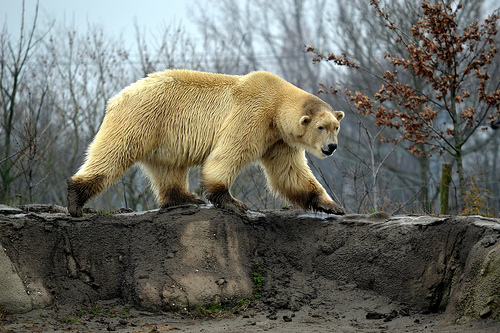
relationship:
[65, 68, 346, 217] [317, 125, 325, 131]
polar bear has eye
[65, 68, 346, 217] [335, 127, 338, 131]
polar bear has eye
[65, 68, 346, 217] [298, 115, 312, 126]
polar bear has ear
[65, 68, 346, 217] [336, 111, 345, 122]
polar bear has ear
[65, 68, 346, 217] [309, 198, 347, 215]
polar bear has paw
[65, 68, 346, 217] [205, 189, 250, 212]
polar bear has paw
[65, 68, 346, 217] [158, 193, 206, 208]
polar bear has paw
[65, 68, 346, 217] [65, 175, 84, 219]
polar bear has paw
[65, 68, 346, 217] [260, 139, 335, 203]
polar bear has leg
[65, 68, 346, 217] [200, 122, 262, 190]
polar bear has leg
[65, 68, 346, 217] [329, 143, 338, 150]
polar bear has nose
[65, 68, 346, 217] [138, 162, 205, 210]
polar bear has leg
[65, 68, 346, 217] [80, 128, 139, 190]
polar bear has leg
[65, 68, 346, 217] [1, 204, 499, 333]
polar bear walk on dirt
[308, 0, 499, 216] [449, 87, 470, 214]
tree has trunk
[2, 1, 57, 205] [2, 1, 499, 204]
tree in background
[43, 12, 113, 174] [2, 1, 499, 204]
tree in background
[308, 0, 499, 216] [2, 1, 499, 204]
tree in background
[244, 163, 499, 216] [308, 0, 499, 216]
fence beside tree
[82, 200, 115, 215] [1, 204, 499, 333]
grass growing in dirt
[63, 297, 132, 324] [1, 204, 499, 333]
grass growing in dirt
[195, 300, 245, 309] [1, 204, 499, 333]
grass growing in dirt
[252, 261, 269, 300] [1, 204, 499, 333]
grass growing in dirt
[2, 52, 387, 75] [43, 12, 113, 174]
power lines above tree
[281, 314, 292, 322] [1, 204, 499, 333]
rock in dirt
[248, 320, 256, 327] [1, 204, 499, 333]
rock in dirt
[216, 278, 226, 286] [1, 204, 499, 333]
rock in dirt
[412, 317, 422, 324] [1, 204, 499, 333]
rock in dirt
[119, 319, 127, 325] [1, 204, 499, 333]
rock in dirt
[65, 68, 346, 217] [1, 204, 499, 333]
polar bear walking on dirt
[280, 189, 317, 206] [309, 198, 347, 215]
fur near paw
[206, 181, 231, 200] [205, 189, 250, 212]
fur near paw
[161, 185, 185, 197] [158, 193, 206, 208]
fur near paw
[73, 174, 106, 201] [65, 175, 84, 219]
fur near paw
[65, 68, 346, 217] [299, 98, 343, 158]
polar bear has head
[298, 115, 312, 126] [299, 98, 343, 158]
ear on head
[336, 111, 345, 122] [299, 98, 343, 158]
ear on head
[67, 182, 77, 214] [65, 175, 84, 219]
bottom of paw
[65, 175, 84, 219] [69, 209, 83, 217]
paw has toes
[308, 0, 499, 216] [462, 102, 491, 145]
tree has branch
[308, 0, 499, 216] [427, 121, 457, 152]
tree has branch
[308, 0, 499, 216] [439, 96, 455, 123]
tree has branch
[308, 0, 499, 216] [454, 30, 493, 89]
tree has branch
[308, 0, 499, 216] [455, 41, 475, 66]
tree has branch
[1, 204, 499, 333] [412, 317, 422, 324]
dirt has rock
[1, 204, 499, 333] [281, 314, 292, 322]
dirt has rock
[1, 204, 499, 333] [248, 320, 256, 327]
dirt has rock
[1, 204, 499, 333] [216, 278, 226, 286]
dirt has rock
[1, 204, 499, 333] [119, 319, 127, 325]
dirt has rock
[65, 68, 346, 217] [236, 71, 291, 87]
polar bear has hump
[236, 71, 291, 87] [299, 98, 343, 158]
hump behind head